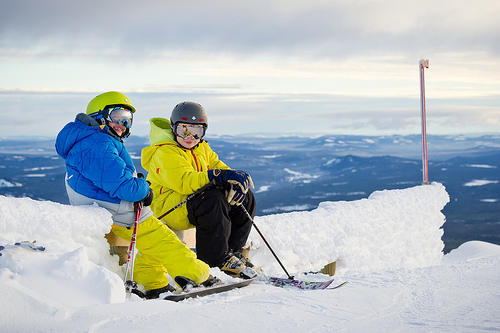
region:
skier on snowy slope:
[52, 82, 211, 294]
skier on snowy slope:
[138, 75, 261, 228]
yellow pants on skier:
[129, 235, 204, 303]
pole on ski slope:
[408, 46, 430, 185]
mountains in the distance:
[262, 90, 410, 182]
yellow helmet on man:
[91, 77, 155, 118]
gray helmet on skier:
[167, 85, 226, 141]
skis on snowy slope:
[166, 252, 338, 331]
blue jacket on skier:
[69, 137, 131, 217]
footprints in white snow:
[338, 233, 453, 328]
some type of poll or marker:
[415, 55, 439, 186]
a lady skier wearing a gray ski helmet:
[145, 100, 231, 172]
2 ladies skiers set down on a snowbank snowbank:
[26, 86, 283, 311]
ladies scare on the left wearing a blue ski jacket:
[48, 85, 158, 216]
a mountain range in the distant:
[252, 117, 412, 177]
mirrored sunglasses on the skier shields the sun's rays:
[102, 105, 139, 131]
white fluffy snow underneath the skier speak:
[0, 299, 499, 330]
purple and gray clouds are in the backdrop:
[0, 0, 495, 57]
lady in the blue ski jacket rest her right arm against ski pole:
[51, 90, 161, 297]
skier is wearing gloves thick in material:
[198, 163, 263, 215]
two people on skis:
[55, 63, 354, 325]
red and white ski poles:
[108, 188, 148, 315]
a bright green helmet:
[68, 74, 153, 126]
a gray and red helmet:
[156, 92, 218, 144]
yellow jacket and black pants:
[131, 117, 270, 284]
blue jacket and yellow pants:
[41, 98, 236, 295]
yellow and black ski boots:
[208, 245, 271, 299]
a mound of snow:
[8, 142, 495, 295]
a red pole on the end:
[403, 53, 450, 200]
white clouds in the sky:
[42, 19, 497, 165]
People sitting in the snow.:
[60, 85, 331, 303]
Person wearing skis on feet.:
[143, 91, 320, 291]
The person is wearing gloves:
[217, 157, 255, 204]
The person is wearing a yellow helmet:
[83, 87, 147, 114]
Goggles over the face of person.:
[171, 118, 216, 140]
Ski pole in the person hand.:
[230, 183, 306, 275]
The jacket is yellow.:
[143, 148, 224, 198]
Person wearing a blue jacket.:
[53, 134, 143, 199]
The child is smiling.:
[86, 106, 156, 139]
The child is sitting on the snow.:
[56, 100, 156, 255]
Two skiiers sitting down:
[1, 84, 499, 331]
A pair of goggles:
[101, 101, 207, 141]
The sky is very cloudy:
[1, 1, 498, 136]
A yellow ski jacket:
[137, 135, 237, 230]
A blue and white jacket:
[52, 111, 154, 229]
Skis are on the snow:
[130, 256, 344, 303]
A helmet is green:
[83, 87, 136, 141]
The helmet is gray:
[168, 98, 209, 138]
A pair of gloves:
[204, 164, 257, 208]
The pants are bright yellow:
[105, 213, 214, 291]